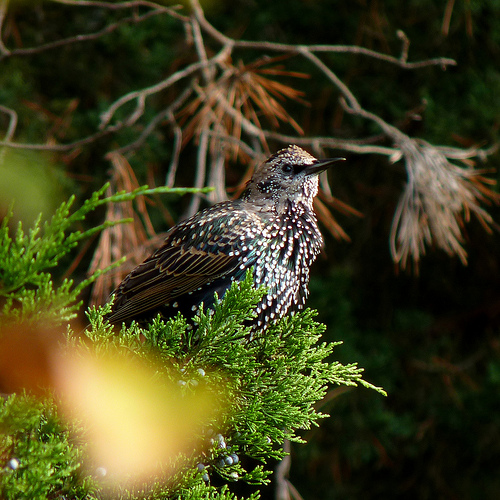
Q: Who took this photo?
A: A man or woman.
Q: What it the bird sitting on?
A: A branch.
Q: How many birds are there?
A: One.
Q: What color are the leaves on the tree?
A: Green.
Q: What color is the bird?
A: Black and white.